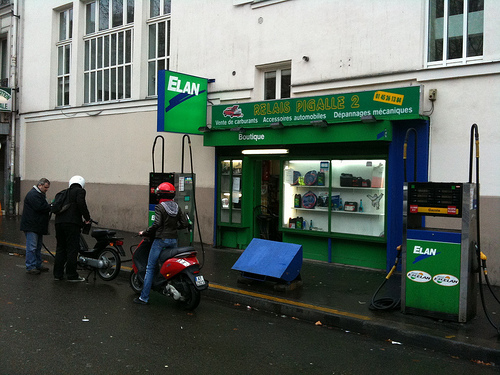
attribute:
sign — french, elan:
[156, 77, 204, 134]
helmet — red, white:
[147, 176, 177, 193]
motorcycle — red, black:
[146, 250, 197, 280]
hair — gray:
[40, 179, 43, 185]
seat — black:
[172, 244, 197, 260]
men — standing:
[12, 167, 193, 289]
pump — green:
[369, 242, 399, 313]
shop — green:
[237, 147, 381, 252]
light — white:
[228, 151, 284, 154]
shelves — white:
[350, 210, 376, 217]